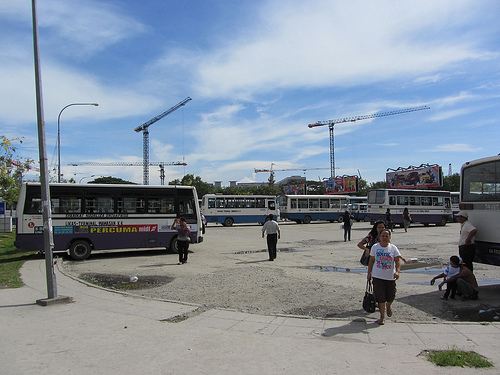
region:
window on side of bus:
[287, 195, 294, 208]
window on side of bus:
[462, 164, 483, 202]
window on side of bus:
[482, 158, 494, 199]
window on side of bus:
[397, 193, 407, 204]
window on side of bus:
[408, 194, 420, 205]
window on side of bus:
[419, 195, 433, 206]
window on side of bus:
[431, 195, 441, 206]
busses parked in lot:
[10, 153, 498, 264]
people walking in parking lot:
[173, 208, 413, 323]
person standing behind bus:
[453, 208, 478, 283]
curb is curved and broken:
[55, 251, 499, 326]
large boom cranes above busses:
[66, 94, 432, 190]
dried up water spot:
[77, 264, 174, 300]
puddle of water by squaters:
[299, 259, 454, 271]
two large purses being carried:
[358, 228, 373, 314]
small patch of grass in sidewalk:
[421, 348, 493, 370]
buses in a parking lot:
[14, 158, 499, 278]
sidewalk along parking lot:
[8, 244, 499, 374]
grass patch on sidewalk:
[411, 342, 492, 373]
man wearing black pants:
[264, 213, 286, 260]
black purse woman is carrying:
[360, 286, 372, 313]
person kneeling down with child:
[425, 245, 475, 300]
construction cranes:
[135, 76, 447, 192]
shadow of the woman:
[320, 312, 376, 347]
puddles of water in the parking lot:
[79, 252, 431, 308]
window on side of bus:
[59, 197, 80, 212]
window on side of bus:
[95, 196, 114, 213]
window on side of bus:
[290, 199, 298, 209]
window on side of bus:
[308, 196, 321, 206]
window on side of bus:
[320, 197, 328, 208]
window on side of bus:
[329, 198, 339, 209]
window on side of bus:
[388, 194, 396, 204]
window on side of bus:
[395, 195, 410, 205]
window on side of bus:
[410, 194, 423, 204]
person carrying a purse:
[360, 227, 404, 326]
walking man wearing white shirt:
[258, 212, 283, 262]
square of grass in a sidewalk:
[416, 342, 496, 371]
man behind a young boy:
[430, 253, 481, 303]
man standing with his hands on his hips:
[450, 208, 479, 276]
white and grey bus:
[13, 179, 205, 261]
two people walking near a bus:
[363, 184, 453, 234]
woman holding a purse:
[357, 218, 387, 267]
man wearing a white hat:
[452, 205, 479, 275]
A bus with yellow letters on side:
[15, 180, 205, 254]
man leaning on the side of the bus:
[453, 208, 483, 275]